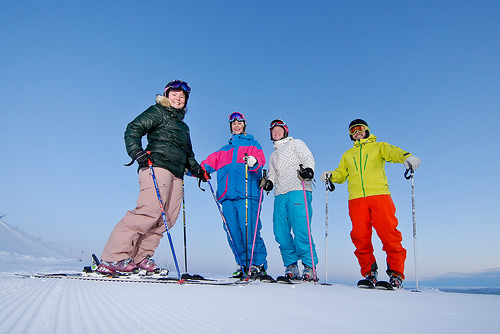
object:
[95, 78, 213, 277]
woman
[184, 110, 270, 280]
woman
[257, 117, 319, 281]
woman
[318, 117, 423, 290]
woman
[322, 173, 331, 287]
ski sticks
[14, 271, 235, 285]
ski boards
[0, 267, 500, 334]
snow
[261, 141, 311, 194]
jacket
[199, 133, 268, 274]
ski outfit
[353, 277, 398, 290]
sets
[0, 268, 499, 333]
clean/white snow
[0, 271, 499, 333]
ground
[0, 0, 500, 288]
clear/blue sky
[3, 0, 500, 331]
picture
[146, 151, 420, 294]
four sets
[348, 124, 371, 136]
ski goggles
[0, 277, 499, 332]
ground snow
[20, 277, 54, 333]
tracks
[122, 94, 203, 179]
black coat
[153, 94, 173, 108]
fur trim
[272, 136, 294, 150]
turtleneck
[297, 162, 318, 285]
pink/ski pole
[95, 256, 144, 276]
pink/ski boots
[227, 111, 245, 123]
blue/ski goggles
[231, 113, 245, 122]
woman's forehead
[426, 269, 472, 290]
mountains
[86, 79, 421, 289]
four people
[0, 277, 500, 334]
ski slope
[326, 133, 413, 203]
snow coat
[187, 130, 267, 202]
snow jacket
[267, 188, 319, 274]
snow pants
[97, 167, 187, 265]
snow pants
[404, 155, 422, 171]
white/snow gloves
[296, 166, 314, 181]
black/snow gloves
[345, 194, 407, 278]
snow pants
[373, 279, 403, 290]
skis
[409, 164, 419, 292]
ski poles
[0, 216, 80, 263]
slope